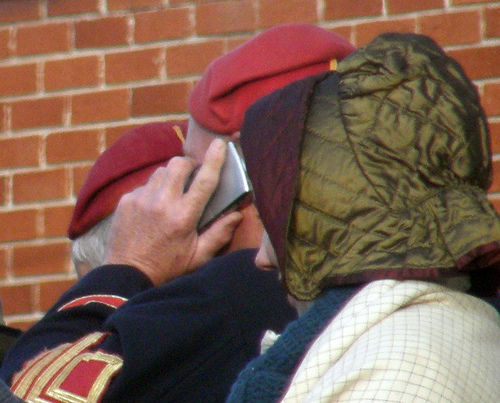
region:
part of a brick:
[70, 96, 80, 119]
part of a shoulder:
[393, 349, 401, 358]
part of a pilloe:
[230, 290, 237, 341]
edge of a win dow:
[366, 346, 398, 386]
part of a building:
[92, 119, 107, 138]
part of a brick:
[97, 165, 109, 195]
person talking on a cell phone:
[174, 146, 243, 213]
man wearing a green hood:
[238, 27, 499, 287]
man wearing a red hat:
[181, 30, 354, 115]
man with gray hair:
[51, 212, 138, 278]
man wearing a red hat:
[41, 109, 223, 215]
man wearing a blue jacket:
[37, 267, 274, 400]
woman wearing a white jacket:
[351, 280, 471, 400]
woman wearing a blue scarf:
[258, 305, 324, 384]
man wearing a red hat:
[193, 46, 327, 93]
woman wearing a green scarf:
[263, 55, 489, 252]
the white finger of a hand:
[119, 188, 134, 203]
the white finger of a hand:
[135, 183, 147, 197]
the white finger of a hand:
[143, 166, 163, 201]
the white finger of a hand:
[165, 155, 187, 200]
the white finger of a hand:
[187, 138, 229, 225]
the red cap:
[64, 118, 199, 237]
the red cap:
[187, 20, 349, 130]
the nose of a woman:
[253, 231, 278, 273]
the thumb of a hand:
[190, 211, 240, 264]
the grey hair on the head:
[70, 216, 117, 265]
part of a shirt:
[450, 335, 460, 343]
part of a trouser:
[202, 228, 212, 250]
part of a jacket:
[326, 240, 329, 263]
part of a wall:
[132, 143, 151, 182]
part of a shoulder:
[353, 332, 364, 352]